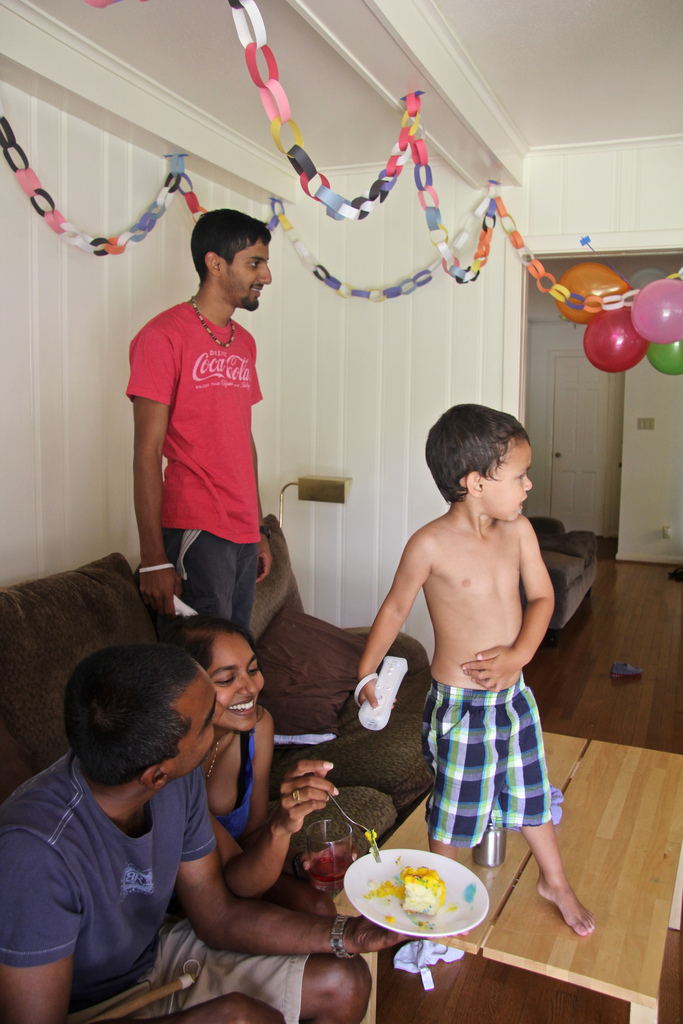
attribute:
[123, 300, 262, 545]
shirt — white, red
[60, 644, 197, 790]
hair — short, black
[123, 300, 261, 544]
t-shirt — red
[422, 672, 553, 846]
shorts — checkered, blue, white, green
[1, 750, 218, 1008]
t-shirt — blue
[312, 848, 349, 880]
liquid — red